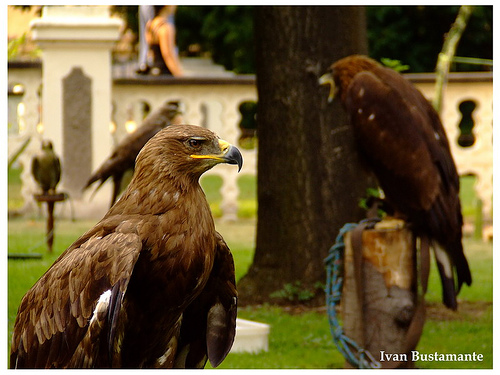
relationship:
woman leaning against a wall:
[130, 0, 179, 70] [105, 65, 275, 232]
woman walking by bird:
[130, 0, 185, 77] [319, 44, 482, 289]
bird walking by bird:
[319, 44, 482, 289] [96, 88, 199, 183]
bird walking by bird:
[96, 88, 199, 183] [17, 109, 261, 373]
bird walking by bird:
[17, 109, 261, 373] [29, 130, 64, 199]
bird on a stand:
[25, 131, 66, 190] [29, 186, 69, 245]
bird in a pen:
[319, 44, 482, 289] [10, 41, 493, 360]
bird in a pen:
[96, 88, 199, 183] [10, 41, 493, 360]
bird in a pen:
[89, 84, 185, 185] [10, 41, 493, 360]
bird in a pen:
[25, 131, 66, 190] [10, 41, 493, 360]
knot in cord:
[320, 245, 338, 262] [320, 219, 360, 358]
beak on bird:
[222, 142, 245, 171] [42, 117, 254, 367]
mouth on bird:
[314, 73, 337, 103] [319, 44, 482, 289]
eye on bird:
[178, 133, 216, 152] [36, 109, 270, 352]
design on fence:
[450, 88, 485, 156] [218, 76, 498, 221]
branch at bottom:
[270, 281, 298, 315] [224, 188, 382, 314]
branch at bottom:
[303, 279, 316, 300] [224, 188, 382, 314]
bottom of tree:
[224, 188, 382, 314] [227, 22, 389, 304]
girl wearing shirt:
[146, 5, 178, 76] [148, 20, 172, 66]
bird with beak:
[17, 109, 261, 373] [204, 134, 245, 177]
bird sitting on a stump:
[319, 44, 482, 289] [335, 215, 436, 360]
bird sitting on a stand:
[25, 131, 66, 190] [31, 188, 72, 243]